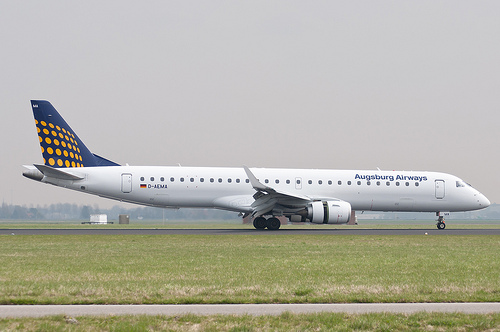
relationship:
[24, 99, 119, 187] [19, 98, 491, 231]
tail of plane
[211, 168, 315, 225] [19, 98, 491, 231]
wing of plane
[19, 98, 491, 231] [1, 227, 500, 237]
plane on runway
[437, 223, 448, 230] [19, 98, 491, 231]
wheel of plane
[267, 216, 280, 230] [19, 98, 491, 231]
wheel of plane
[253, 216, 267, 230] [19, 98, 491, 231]
wheel of plane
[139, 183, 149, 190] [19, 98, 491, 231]
flag on plane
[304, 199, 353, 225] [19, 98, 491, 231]
engine of plane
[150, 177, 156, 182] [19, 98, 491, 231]
window of plane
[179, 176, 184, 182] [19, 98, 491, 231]
window of plane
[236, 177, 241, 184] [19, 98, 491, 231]
window of plane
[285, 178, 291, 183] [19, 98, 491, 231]
window of plane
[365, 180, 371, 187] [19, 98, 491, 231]
window of plane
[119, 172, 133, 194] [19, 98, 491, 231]
backdoor of plane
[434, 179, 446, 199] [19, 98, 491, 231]
front door of plane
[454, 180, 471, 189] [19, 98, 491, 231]
cockpit of plane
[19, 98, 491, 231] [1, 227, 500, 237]
plane sits on runway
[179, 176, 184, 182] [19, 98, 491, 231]
window on plane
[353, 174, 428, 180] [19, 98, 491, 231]
augsburg airways on plane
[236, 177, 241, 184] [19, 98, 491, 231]
window on plane